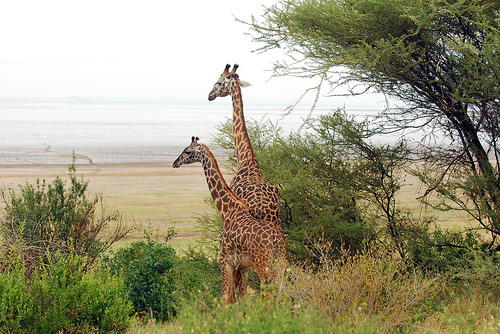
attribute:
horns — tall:
[208, 48, 264, 97]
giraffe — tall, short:
[208, 64, 280, 237]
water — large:
[115, 97, 180, 137]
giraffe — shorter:
[172, 136, 287, 308]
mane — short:
[202, 143, 250, 210]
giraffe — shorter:
[167, 134, 289, 298]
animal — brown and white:
[161, 132, 283, 307]